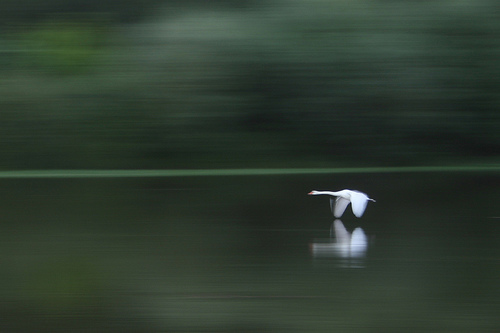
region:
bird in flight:
[297, 158, 394, 267]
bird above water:
[269, 149, 435, 266]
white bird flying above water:
[270, 145, 440, 283]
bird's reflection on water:
[276, 137, 401, 310]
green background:
[80, 189, 240, 302]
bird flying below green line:
[303, 150, 395, 255]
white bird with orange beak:
[300, 155, 396, 265]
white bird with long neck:
[292, 140, 449, 267]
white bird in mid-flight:
[267, 141, 429, 230]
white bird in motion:
[240, 137, 497, 262]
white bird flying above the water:
[299, 179, 381, 238]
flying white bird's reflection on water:
[294, 208, 387, 271]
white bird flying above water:
[298, 178, 388, 214]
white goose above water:
[295, 155, 380, 226]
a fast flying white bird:
[296, 171, 381, 221]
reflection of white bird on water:
[300, 217, 391, 272]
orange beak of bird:
[301, 180, 311, 200]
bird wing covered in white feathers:
[345, 190, 366, 215]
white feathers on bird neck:
[315, 185, 335, 200]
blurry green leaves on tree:
[0, 15, 106, 70]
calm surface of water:
[95, 180, 245, 295]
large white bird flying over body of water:
[300, 180, 381, 230]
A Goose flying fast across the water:
[294, 170, 396, 230]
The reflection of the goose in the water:
[306, 221, 378, 273]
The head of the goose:
[308, 187, 329, 199]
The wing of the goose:
[351, 191, 369, 216]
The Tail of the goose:
[358, 190, 379, 207]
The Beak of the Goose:
[306, 189, 312, 197]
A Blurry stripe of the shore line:
[0, 162, 499, 186]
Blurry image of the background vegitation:
[0, 14, 490, 134]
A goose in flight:
[306, 176, 374, 223]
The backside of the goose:
[334, 185, 378, 197]